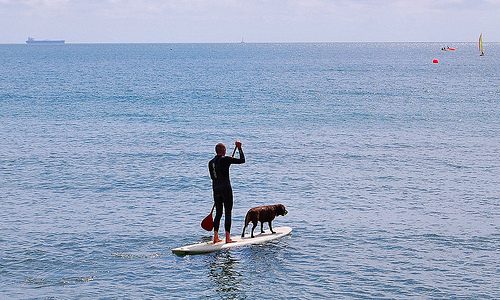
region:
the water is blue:
[360, 174, 461, 281]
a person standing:
[206, 148, 239, 240]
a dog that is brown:
[243, 195, 290, 237]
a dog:
[247, 205, 290, 237]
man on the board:
[190, 114, 263, 244]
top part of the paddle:
[191, 198, 218, 242]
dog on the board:
[235, 176, 301, 247]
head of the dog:
[268, 195, 298, 225]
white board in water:
[173, 221, 293, 283]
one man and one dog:
[164, 71, 339, 248]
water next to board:
[321, 166, 403, 278]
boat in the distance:
[5, 18, 97, 61]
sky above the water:
[132, 3, 285, 33]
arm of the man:
[228, 134, 257, 172]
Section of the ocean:
[20, 205, 139, 285]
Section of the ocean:
[341, 222, 473, 299]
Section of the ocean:
[351, 123, 468, 213]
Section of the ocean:
[294, 71, 432, 175]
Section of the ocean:
[51, 50, 190, 136]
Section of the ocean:
[190, 46, 310, 109]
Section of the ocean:
[4, 42, 132, 200]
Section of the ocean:
[295, 112, 431, 298]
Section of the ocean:
[381, 72, 496, 289]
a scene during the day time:
[9, 15, 493, 297]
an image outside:
[13, 8, 468, 297]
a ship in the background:
[14, 14, 88, 68]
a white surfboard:
[162, 215, 311, 288]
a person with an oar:
[165, 110, 255, 248]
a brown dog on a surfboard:
[239, 197, 311, 252]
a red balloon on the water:
[417, 55, 458, 70]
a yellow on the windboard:
[474, 27, 499, 74]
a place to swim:
[2, 8, 499, 258]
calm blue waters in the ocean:
[333, 199, 404, 229]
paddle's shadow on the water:
[211, 255, 245, 287]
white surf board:
[165, 229, 312, 252]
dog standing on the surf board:
[238, 198, 304, 238]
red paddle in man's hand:
[188, 198, 228, 240]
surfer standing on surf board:
[191, 134, 244, 218]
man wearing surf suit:
[192, 155, 247, 202]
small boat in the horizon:
[469, 30, 488, 76]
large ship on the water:
[13, 28, 79, 51]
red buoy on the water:
[421, 53, 446, 72]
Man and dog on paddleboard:
[170, 139, 294, 255]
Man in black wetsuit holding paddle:
[199, 141, 245, 243]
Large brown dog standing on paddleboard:
[241, 203, 289, 239]